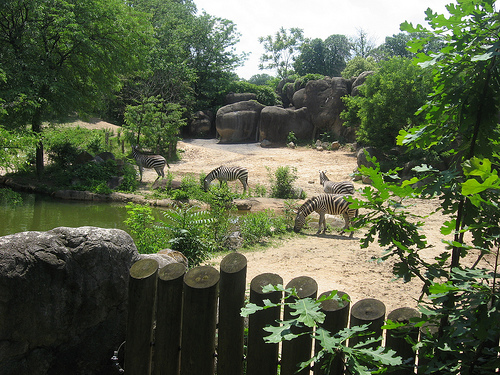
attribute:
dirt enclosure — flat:
[178, 125, 450, 237]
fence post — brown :
[312, 286, 347, 371]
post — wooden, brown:
[214, 249, 247, 374]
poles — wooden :
[147, 250, 246, 336]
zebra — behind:
[124, 145, 172, 180]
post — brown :
[353, 296, 383, 364]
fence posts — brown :
[116, 250, 197, 367]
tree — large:
[4, 7, 136, 113]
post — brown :
[180, 264, 219, 374]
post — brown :
[113, 230, 494, 374]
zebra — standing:
[241, 135, 398, 274]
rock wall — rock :
[201, 75, 399, 151]